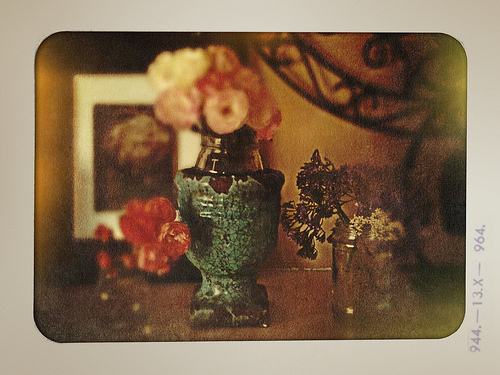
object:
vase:
[170, 163, 287, 327]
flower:
[201, 86, 249, 136]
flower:
[147, 47, 212, 92]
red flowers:
[155, 220, 194, 255]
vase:
[329, 215, 423, 324]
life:
[27, 20, 473, 343]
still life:
[35, 28, 466, 340]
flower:
[133, 244, 172, 276]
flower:
[141, 196, 177, 224]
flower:
[126, 197, 145, 218]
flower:
[93, 225, 117, 245]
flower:
[280, 195, 335, 260]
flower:
[295, 148, 350, 210]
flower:
[373, 205, 388, 215]